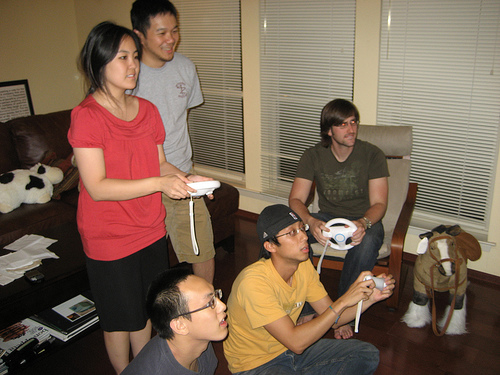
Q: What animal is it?
A: Stuffed horse with saddle.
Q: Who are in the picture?
A: Group of friends engaged in playing video game.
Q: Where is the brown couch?
A: Against wall of room.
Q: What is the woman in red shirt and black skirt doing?
A: Playing wii.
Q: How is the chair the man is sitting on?
A: Brown wooden frame with beige cushion.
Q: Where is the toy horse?
A: In the living room.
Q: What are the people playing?
A: Video games.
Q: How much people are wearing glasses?
A: Three.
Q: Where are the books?
A: On the coffee table.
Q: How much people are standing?
A: Two.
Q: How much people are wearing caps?
A: One.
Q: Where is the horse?
A: On the man's left.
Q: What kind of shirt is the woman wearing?
A: A short sleeve.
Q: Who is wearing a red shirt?
A: The woman.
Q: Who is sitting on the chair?
A: The man.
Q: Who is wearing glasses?
A: The two nearest men.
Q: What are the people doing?
A: Playing a video game.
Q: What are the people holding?
A: Game controllers.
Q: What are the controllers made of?
A: Plastic.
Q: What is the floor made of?
A: Wood.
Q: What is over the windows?
A: Blinds.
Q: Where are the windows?
A: Behind the blinds.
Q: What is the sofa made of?
A: Leather.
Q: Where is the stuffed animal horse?
A: On the floor.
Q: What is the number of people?
A: Five.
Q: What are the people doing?
A: Playing a video game.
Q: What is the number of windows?
A: Three.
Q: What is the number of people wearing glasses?
A: Three.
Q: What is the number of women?
A: One.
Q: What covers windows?
A: Blinds.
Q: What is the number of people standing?
A: Two.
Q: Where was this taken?
A: A private residence.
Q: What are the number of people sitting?
A: Three.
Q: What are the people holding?
A: Wii remotes or wheels.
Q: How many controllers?
A: 3.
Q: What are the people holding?
A: Controllers.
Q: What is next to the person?
A: Stuffed horse.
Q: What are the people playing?
A: A game.